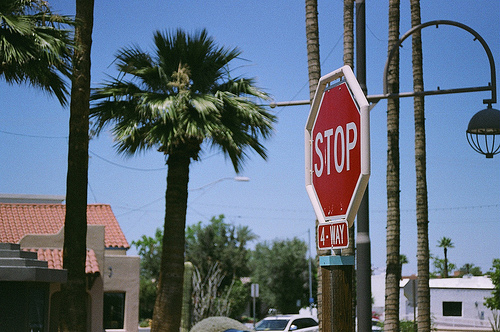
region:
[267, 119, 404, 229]
this is a stop sign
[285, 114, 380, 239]
the stop sign is red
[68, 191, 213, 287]
this is a palm tree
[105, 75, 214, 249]
the tree is brown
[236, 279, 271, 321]
this is a sign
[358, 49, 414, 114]
this is a pole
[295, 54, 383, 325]
STREET SIGN AT TOP OF POST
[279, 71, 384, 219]
THE STREET SIGN IS A STOP SIGN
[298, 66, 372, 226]
THE STREET SIGN IS OCTAGONAL IN SHAPE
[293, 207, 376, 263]
SMALL SIGN ON POST INDICATES THAT THIS IS A 4-WAY STOP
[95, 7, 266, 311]
TALL PALM TREE NEAR STOP SIGN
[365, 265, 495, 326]
WHITE BUILDING BEHIND STOP SIGN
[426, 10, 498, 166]
STREET LIGHT HANGING FROM CURVED POLE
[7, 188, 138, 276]
RED ROOF ON TOP OF BUILDING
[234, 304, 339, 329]
WHITE CAR ON STREET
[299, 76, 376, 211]
a small red stop sign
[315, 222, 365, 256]
a small red four way intersection sign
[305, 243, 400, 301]
a skinny gray metal pole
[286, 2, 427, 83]
a bunch of skinny tree trunks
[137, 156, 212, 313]
a thick palm tree trunk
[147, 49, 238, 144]
a bunch of leave on a palm tree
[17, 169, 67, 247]
a red tile roof of a house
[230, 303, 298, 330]
a small white car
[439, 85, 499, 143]
a small gray lamp post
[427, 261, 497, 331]
a small white house with a window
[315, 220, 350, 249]
a red sign that says 4-way in white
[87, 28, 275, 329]
a green palm tree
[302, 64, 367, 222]
a red STOP sign with a white border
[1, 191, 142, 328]
a tan building with a red roof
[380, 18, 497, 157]
a light on a metal pole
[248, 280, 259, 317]
the back of a sign on a metal pole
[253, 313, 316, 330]
a white car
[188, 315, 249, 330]
a large gray rock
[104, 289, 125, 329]
a rectangular window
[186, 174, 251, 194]
a white street light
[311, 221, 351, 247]
Small 4-Way red and white sign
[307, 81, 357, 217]
Red and White stop sign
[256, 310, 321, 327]
White car on street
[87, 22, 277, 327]
Large Palm tree on corner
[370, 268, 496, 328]
White building on corner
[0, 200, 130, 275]
Red tile roof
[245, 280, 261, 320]
Sign post on street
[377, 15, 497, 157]
Hanging street light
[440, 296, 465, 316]
Window in white building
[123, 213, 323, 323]
Trees lining the street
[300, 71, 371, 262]
a white framed stop sign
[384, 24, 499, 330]
a curved street light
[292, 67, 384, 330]
a red and white stop sign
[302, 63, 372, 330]
red stop sign with white frame on wood pole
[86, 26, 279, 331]
palm tree with brown trunk and green leaves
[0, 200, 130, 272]
red terra cotta ceramic roof